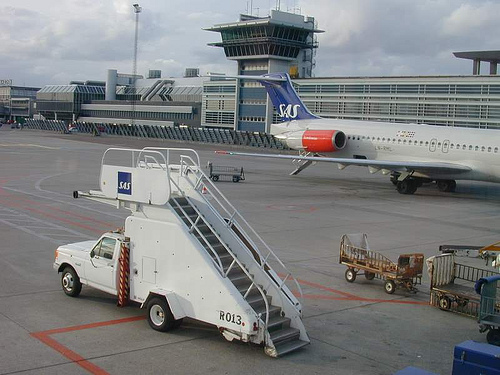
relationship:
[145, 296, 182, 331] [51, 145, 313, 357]
tire of van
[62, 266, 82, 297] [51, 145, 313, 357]
front tire of van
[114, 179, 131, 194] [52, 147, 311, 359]
text in car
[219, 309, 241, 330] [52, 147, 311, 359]
number of car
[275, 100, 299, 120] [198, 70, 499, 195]
display on airplane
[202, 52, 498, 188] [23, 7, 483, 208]
airplane in an airport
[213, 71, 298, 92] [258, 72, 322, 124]
horizontal fins on crate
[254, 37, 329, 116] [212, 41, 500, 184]
stabilizer on plane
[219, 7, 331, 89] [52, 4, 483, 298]
tower on airport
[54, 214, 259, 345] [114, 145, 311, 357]
car carrying stairs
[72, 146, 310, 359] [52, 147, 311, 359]
mobile stairs on a car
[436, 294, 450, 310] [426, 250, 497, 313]
black wheel on luggage car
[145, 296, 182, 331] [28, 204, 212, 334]
tire on car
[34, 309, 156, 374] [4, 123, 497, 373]
red line on street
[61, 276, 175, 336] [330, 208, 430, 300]
wheels on cart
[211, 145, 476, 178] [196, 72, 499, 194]
wing of an airplane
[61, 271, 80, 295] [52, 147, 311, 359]
front tire on car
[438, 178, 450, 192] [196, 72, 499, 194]
wheel on airplane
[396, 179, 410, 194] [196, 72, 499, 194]
wheel on airplane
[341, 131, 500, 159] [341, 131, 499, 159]
passengers for passengers